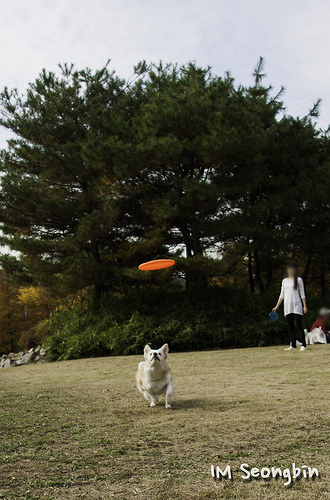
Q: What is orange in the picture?
A: A frisbee.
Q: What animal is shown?
A: A dog.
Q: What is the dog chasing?
A: A frisbee.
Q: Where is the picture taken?
A: A park.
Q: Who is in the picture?
A: A woman.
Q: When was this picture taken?
A: Daytime.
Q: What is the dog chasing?
A: A Frisbee.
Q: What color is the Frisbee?
A: Orange.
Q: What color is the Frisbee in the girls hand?
A: Blue.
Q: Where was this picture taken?
A: A park.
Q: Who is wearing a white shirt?
A: The woman.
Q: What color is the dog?
A: White.